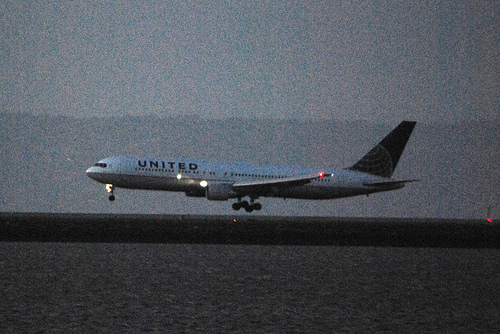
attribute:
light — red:
[481, 212, 496, 227]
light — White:
[102, 180, 113, 192]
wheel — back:
[231, 199, 238, 211]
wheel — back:
[238, 197, 248, 207]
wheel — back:
[243, 204, 256, 214]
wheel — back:
[251, 200, 264, 212]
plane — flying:
[71, 97, 448, 234]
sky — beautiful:
[86, 41, 333, 100]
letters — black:
[135, 155, 200, 175]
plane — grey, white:
[77, 109, 428, 223]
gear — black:
[105, 185, 262, 212]